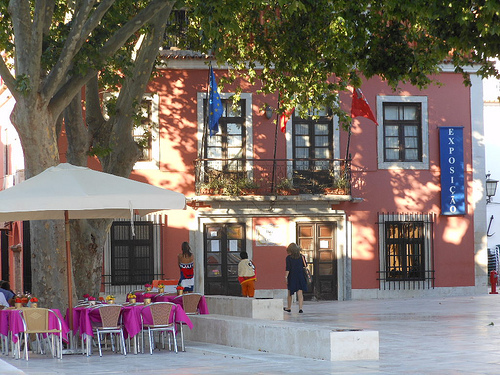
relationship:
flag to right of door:
[344, 72, 374, 128] [282, 80, 343, 194]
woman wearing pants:
[237, 248, 257, 298] [234, 273, 258, 297]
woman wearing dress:
[283, 241, 308, 313] [287, 252, 307, 292]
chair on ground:
[141, 295, 194, 351] [12, 325, 499, 372]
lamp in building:
[485, 179, 499, 206] [77, 28, 498, 298]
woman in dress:
[283, 241, 308, 313] [280, 257, 308, 293]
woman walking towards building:
[283, 241, 308, 313] [53, 17, 492, 294]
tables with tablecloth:
[80, 304, 181, 355] [69, 305, 143, 338]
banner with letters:
[423, 117, 483, 217] [444, 128, 459, 211]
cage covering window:
[377, 208, 437, 289] [374, 210, 435, 286]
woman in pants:
[234, 248, 259, 298] [237, 276, 256, 297]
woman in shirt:
[234, 248, 259, 298] [235, 261, 255, 281]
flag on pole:
[207, 65, 225, 138] [198, 62, 218, 161]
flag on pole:
[350, 85, 379, 125] [344, 115, 352, 168]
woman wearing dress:
[278, 244, 318, 313] [281, 260, 310, 290]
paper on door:
[209, 228, 222, 254] [203, 225, 244, 289]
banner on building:
[423, 117, 483, 217] [0, 50, 486, 300]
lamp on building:
[478, 165, 498, 209] [0, 50, 486, 300]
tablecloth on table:
[65, 303, 141, 334] [69, 305, 126, 355]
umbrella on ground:
[1, 161, 188, 236] [3, 289, 497, 371]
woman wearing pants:
[237, 248, 257, 298] [234, 272, 262, 300]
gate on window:
[374, 206, 440, 296] [388, 222, 429, 278]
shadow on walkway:
[356, 303, 465, 326] [0, 287, 499, 374]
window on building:
[287, 108, 338, 183] [127, 9, 477, 315]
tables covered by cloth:
[80, 304, 181, 355] [44, 307, 66, 339]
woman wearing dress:
[283, 241, 308, 313] [276, 250, 316, 300]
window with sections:
[294, 124, 309, 135] [309, 136, 337, 152]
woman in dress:
[283, 241, 308, 313] [276, 250, 319, 280]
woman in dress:
[283, 241, 308, 313] [276, 254, 306, 278]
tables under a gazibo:
[0, 294, 188, 357] [0, 159, 190, 244]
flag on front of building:
[207, 61, 225, 135] [6, 20, 482, 298]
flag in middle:
[271, 85, 299, 138] [188, 61, 381, 181]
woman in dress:
[283, 241, 308, 313] [285, 252, 305, 293]